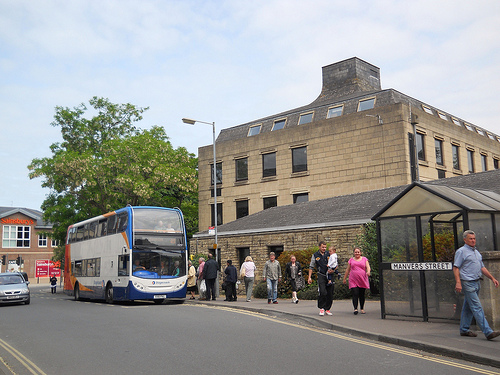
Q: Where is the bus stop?
A: Right of the lady in pink.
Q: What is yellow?
A: The lines on the road.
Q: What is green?
A: Trees.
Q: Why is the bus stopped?
A: Unloading.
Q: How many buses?
A: One.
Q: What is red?
A: The house.